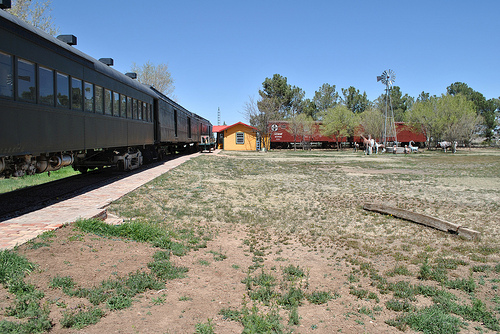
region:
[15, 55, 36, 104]
window on the black passenger car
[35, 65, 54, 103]
window on the black passenger car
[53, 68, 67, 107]
window on the black passenger car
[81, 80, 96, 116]
window on the black passenger car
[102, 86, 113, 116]
window on the black passenger car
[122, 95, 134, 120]
window on the black passenger car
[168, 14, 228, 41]
white clouds in blue sky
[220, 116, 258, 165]
yellow and red building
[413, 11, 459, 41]
white clouds in blue sky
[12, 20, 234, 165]
the train is black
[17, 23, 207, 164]
the train is black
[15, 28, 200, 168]
the train is black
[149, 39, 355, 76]
the sky is clear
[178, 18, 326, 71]
the sky is clear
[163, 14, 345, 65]
the sky is clear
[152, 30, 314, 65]
the sky is clear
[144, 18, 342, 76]
the sky is clear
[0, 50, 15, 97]
glass window on train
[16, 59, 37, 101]
glass window on train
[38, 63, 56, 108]
glass window on train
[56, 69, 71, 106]
glass window on train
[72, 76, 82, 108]
glass window on train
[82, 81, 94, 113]
glass window on train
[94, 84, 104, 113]
glass window on train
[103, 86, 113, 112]
glass window on train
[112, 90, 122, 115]
glass window on train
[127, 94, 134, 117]
glass window on train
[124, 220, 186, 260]
green bush on the ground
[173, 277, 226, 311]
brown sand on the ground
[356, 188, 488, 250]
silver object on the ground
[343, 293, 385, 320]
tiny pebbles on the ground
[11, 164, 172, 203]
clear path on the ground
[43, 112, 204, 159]
large train on the track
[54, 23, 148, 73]
boxes on top of car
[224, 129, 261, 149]
orange color on house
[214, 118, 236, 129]
red color on the roof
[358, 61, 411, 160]
tall weather vane on the ground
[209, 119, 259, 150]
yellow and red building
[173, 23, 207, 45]
white clouds in blue sky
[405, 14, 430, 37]
white clouds in blue sky